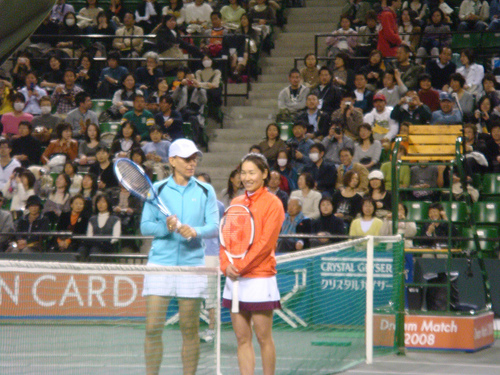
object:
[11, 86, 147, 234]
audience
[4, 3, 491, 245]
stands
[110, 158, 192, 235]
racket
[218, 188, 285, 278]
orange jacket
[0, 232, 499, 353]
advertisements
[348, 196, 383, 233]
woman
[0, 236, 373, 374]
net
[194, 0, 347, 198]
steps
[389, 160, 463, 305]
platform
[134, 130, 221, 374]
player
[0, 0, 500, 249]
rows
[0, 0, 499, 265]
chair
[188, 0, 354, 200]
stairs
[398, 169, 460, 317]
ladder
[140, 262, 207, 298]
shorts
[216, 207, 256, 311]
racket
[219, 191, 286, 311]
body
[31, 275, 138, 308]
card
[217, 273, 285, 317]
skirt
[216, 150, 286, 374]
woman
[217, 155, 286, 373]
player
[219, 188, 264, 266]
top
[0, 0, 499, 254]
people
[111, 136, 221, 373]
woman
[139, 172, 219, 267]
jacket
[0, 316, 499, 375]
court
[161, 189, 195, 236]
top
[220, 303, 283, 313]
trim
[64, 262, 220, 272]
partition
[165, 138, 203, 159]
cap